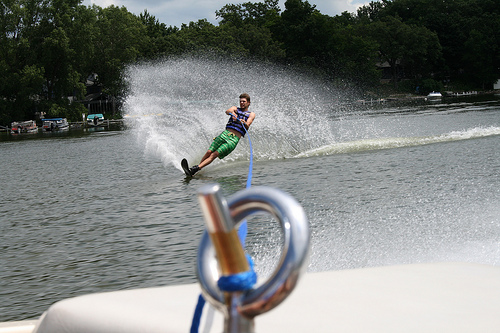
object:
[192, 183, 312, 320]
ring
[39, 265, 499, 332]
boat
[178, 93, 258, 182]
man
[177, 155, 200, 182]
water skiis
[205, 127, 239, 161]
swim trunks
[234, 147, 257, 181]
rope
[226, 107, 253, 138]
vest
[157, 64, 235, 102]
splash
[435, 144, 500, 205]
water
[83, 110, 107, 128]
boat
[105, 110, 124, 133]
dock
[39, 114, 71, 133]
boat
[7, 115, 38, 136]
boat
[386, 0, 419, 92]
trees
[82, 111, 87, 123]
pilings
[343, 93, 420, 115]
shore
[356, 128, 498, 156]
wake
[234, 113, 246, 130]
buckles